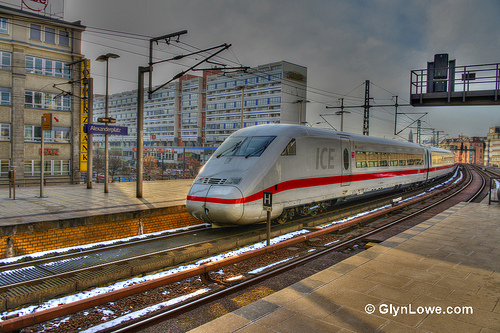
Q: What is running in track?
A: Train.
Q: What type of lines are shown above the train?
A: Power.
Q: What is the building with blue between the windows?
A: Apartments.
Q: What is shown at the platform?
A: Train.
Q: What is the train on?
A: Track.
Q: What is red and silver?
A: Train.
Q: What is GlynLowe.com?
A: Owner of photo.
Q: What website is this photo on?
A: GlynLowe.com.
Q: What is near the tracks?
A: Buildings.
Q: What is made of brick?
A: Platform.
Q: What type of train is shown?
A: Bullet train.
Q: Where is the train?
A: On the train tracks.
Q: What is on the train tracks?
A: A train.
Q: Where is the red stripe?
A: On the train.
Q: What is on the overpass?
A: A sign.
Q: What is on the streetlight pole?
A: A blue sign.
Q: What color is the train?
A: Grey.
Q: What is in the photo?
A: Train.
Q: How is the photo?
A: Clear.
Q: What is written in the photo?
A: Glynlowe.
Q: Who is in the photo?
A: Nobody.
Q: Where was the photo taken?
A: In a city.